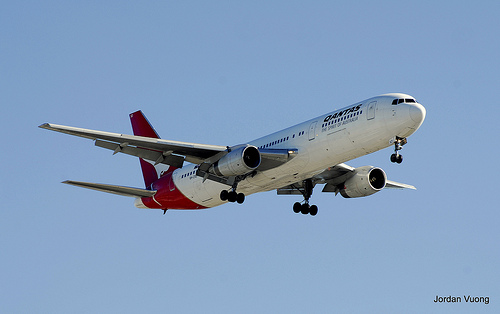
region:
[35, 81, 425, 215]
red and white aircraft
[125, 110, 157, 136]
plane tail is red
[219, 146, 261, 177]
silver intake for plane engine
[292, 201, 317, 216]
three black wheels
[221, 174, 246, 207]
exposed landing gear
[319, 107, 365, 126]
Logo print on plane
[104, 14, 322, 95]
skies are clear and blue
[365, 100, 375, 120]
Emergency escape door hatch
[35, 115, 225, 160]
right wing of plane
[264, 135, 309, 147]
passenger windows on plane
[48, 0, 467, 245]
commuter jet mid flight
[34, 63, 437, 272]
landing gear down on jet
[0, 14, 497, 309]
plane flying through air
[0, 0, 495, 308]
blue, cloud free sky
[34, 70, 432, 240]
company name of qantas on plane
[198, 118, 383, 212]
turbine engines moving quickly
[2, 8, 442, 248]
plane with red on back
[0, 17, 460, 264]
sun reflecting off of plane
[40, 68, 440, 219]
exit door closed on plane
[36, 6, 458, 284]
silver wings on white and red plane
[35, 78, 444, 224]
airplane flying through the air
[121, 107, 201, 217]
red portion of airplane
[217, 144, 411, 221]
wheels of airplane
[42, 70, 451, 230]
white, gray, and red airplane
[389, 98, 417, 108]
front windows of airplane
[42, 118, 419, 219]
wings of the airplane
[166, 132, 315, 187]
row of tiny windows on plane's side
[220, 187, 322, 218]
two sets of three wheels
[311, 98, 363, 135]
airplane's logo on side of plane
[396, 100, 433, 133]
white nose of airplane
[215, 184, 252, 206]
wheels on bottom of plane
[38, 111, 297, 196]
large wing on plane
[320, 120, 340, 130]
windows on the plane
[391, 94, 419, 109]
windshield window on plane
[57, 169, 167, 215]
fin on the back of plane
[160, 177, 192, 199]
red and white paint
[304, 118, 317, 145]
passenger exit door of plane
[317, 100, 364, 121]
Qantas painted on plane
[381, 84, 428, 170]
front of plane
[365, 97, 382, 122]
front door of plane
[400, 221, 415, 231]
part of the sky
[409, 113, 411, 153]
tip of a plane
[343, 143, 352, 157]
part of a plane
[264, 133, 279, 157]
side of a plane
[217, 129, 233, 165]
edge of a plane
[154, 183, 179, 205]
back of a plane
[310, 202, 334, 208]
part of a wheel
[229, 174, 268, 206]
edge of a wheel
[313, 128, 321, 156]
side of a plane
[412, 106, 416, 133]
tip of a plane